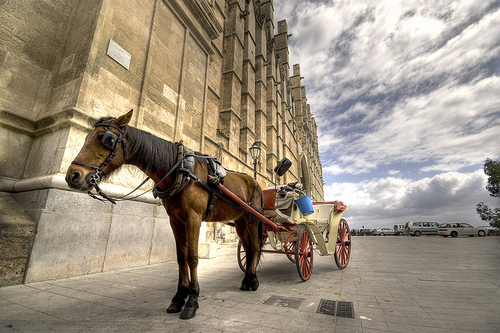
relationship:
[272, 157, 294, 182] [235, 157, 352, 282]
mirror on carriage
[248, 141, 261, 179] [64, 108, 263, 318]
lamp behind horse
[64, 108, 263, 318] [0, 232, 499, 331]
horse in ground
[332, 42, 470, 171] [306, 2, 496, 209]
clouds in sky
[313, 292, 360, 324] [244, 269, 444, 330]
drainage on ground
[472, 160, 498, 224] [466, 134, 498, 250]
tree on side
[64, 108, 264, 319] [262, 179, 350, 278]
horse near carriage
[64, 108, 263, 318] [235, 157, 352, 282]
horse pull carriage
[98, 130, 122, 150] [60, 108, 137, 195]
block on face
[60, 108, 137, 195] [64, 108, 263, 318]
face on horse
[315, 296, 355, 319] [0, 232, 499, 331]
grate on ground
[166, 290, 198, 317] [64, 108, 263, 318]
hooves on horse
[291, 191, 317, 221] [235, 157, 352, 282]
bucket on carriage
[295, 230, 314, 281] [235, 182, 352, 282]
spokes wheel on wagon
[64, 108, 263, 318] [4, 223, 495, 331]
horse on stone road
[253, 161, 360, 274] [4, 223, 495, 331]
carriage on stone road